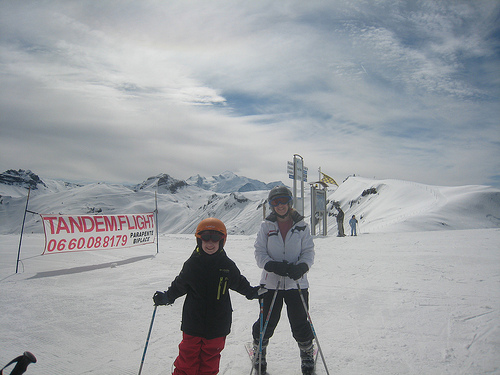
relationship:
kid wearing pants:
[152, 219, 270, 374] [170, 330, 226, 373]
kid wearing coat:
[152, 219, 270, 374] [162, 241, 258, 339]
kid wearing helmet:
[152, 219, 270, 374] [195, 216, 226, 255]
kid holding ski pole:
[152, 219, 270, 374] [136, 301, 158, 374]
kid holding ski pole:
[152, 219, 270, 374] [254, 296, 262, 374]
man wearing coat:
[251, 185, 315, 374] [254, 213, 316, 292]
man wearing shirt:
[251, 185, 315, 374] [275, 217, 295, 242]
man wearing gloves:
[251, 185, 315, 374] [263, 260, 308, 281]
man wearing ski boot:
[251, 185, 315, 374] [251, 338, 270, 373]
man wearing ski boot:
[251, 185, 315, 374] [294, 339, 317, 375]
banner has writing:
[16, 208, 158, 262] [44, 215, 157, 254]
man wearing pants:
[251, 185, 315, 374] [251, 286, 313, 341]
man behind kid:
[251, 185, 315, 374] [152, 219, 270, 374]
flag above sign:
[320, 171, 337, 188] [308, 184, 328, 237]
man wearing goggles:
[251, 185, 315, 374] [267, 194, 289, 207]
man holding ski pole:
[251, 185, 315, 374] [295, 278, 330, 374]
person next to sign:
[334, 207, 345, 236] [308, 184, 328, 237]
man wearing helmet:
[251, 185, 315, 374] [267, 186, 294, 218]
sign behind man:
[308, 184, 328, 237] [251, 185, 315, 374]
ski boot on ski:
[251, 338, 270, 373] [243, 338, 256, 359]